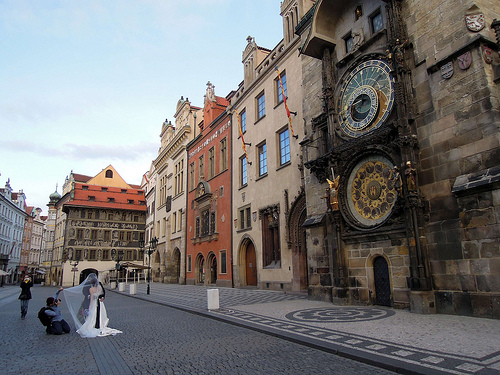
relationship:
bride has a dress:
[86, 277, 105, 329] [77, 291, 121, 336]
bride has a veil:
[86, 277, 105, 329] [60, 272, 99, 326]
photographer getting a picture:
[34, 294, 73, 337] [55, 300, 63, 307]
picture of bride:
[55, 300, 63, 307] [86, 277, 105, 329]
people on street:
[15, 271, 36, 321] [4, 280, 407, 372]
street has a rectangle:
[4, 280, 407, 372] [204, 286, 224, 312]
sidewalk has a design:
[114, 277, 500, 373] [274, 299, 402, 327]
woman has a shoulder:
[86, 277, 105, 329] [96, 281, 106, 290]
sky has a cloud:
[2, 5, 243, 188] [2, 137, 159, 176]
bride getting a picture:
[86, 277, 105, 329] [55, 300, 63, 307]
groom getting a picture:
[77, 270, 99, 324] [55, 300, 63, 307]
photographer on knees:
[34, 294, 73, 337] [55, 323, 72, 333]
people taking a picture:
[15, 271, 36, 321] [24, 280, 32, 283]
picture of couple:
[55, 300, 63, 307] [63, 268, 133, 340]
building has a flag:
[137, 163, 159, 283] [142, 171, 155, 187]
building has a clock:
[291, 7, 499, 312] [337, 61, 398, 138]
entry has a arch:
[360, 248, 401, 312] [367, 245, 394, 272]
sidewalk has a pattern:
[114, 277, 500, 373] [131, 281, 500, 370]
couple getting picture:
[63, 268, 133, 340] [55, 300, 63, 307]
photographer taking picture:
[34, 294, 73, 337] [55, 300, 63, 307]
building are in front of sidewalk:
[291, 0, 500, 314] [114, 277, 500, 373]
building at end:
[66, 165, 149, 282] [11, 281, 115, 295]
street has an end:
[4, 280, 407, 372] [11, 281, 115, 295]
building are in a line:
[291, 0, 500, 314] [148, 162, 499, 191]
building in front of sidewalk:
[291, 0, 500, 314] [114, 277, 500, 373]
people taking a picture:
[15, 271, 36, 321] [55, 300, 63, 307]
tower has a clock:
[308, 8, 416, 237] [337, 61, 398, 138]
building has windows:
[291, 7, 499, 312] [336, 11, 400, 52]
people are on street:
[17, 255, 143, 368] [4, 280, 407, 372]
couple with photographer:
[63, 268, 133, 340] [34, 294, 73, 337]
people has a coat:
[15, 271, 36, 321] [19, 281, 33, 300]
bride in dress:
[86, 277, 105, 329] [77, 291, 121, 336]